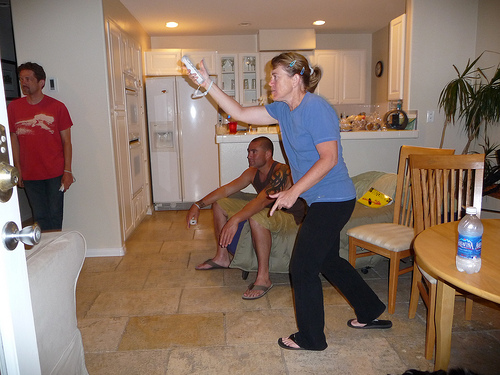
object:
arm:
[233, 162, 291, 219]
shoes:
[277, 332, 328, 352]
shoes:
[194, 258, 229, 269]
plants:
[432, 44, 497, 194]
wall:
[398, 2, 495, 154]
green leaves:
[451, 79, 491, 102]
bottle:
[455, 206, 484, 273]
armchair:
[213, 161, 406, 280]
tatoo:
[264, 161, 292, 195]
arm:
[201, 167, 256, 209]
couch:
[226, 170, 457, 275]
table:
[412, 204, 499, 374]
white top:
[465, 205, 476, 216]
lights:
[168, 21, 180, 31]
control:
[180, 57, 206, 84]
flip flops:
[242, 278, 274, 300]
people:
[180, 50, 395, 352]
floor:
[81, 209, 498, 375]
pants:
[288, 198, 387, 346]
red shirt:
[7, 93, 73, 181]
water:
[455, 223, 484, 275]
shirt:
[264, 90, 357, 206]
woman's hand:
[180, 56, 204, 86]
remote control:
[190, 219, 197, 226]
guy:
[7, 61, 75, 230]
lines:
[172, 284, 190, 308]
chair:
[346, 143, 454, 315]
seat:
[346, 216, 418, 252]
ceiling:
[121, 0, 408, 31]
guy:
[185, 135, 293, 299]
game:
[180, 55, 215, 99]